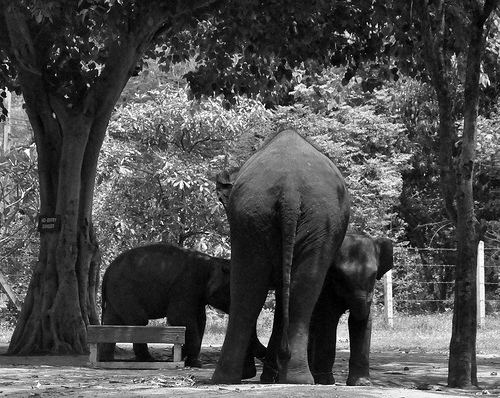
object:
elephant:
[211, 128, 349, 384]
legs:
[349, 307, 372, 372]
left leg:
[216, 255, 270, 370]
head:
[329, 238, 393, 305]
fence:
[390, 246, 500, 319]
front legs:
[186, 307, 206, 359]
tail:
[281, 195, 301, 349]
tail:
[101, 273, 107, 326]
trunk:
[349, 288, 370, 320]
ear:
[375, 238, 394, 281]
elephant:
[302, 229, 402, 388]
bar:
[86, 325, 185, 369]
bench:
[87, 325, 187, 369]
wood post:
[87, 325, 185, 369]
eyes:
[334, 269, 345, 280]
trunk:
[252, 330, 267, 362]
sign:
[38, 216, 61, 233]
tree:
[0, 0, 500, 388]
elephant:
[101, 244, 268, 367]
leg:
[122, 317, 150, 354]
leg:
[98, 318, 120, 355]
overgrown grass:
[200, 315, 500, 356]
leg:
[306, 307, 341, 371]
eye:
[369, 271, 376, 279]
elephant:
[308, 232, 394, 387]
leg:
[278, 260, 330, 367]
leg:
[265, 281, 289, 364]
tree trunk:
[7, 110, 112, 357]